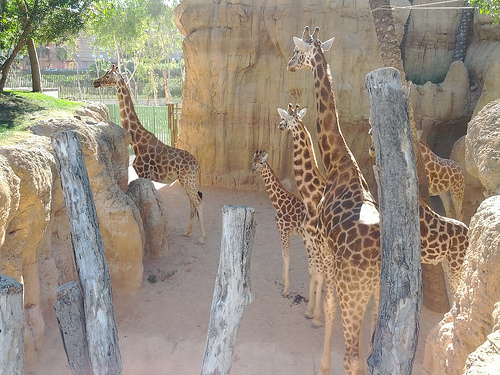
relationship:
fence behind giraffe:
[111, 106, 179, 150] [287, 26, 379, 374]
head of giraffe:
[285, 25, 336, 74] [287, 26, 379, 374]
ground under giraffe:
[30, 165, 443, 372] [287, 26, 379, 374]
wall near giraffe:
[176, 2, 497, 202] [287, 26, 379, 374]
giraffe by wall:
[287, 26, 379, 374] [176, 2, 497, 202]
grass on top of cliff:
[1, 90, 82, 153] [2, 102, 146, 365]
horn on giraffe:
[302, 25, 311, 38] [287, 26, 379, 374]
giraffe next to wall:
[287, 26, 379, 374] [176, 2, 497, 202]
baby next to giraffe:
[249, 148, 321, 316] [287, 26, 379, 374]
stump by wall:
[357, 66, 423, 375] [176, 2, 497, 202]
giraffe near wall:
[287, 26, 379, 374] [176, 2, 497, 202]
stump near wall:
[357, 66, 423, 375] [176, 2, 497, 202]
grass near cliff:
[1, 90, 82, 153] [2, 102, 146, 365]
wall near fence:
[176, 2, 497, 202] [111, 106, 179, 150]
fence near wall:
[111, 106, 179, 150] [176, 2, 497, 202]